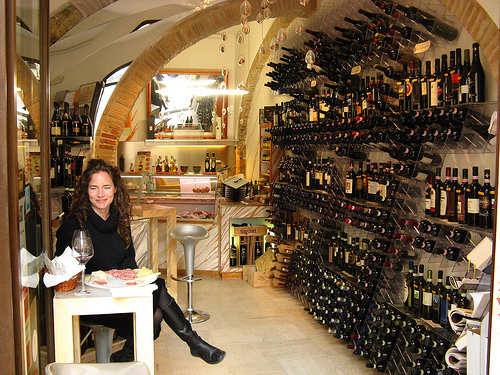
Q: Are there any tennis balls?
A: No, there are no tennis balls.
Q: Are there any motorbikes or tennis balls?
A: No, there are no tennis balls or motorbikes.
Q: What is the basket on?
A: The basket is on the table.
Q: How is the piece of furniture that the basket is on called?
A: The piece of furniture is a table.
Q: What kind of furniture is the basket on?
A: The basket is on the table.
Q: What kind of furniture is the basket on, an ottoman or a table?
A: The basket is on a table.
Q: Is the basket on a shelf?
A: No, the basket is on the table.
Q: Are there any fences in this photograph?
A: No, there are no fences.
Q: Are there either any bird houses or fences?
A: No, there are no fences or bird houses.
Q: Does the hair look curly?
A: Yes, the hair is curly.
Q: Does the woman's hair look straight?
A: No, the hair is curly.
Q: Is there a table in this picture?
A: Yes, there is a table.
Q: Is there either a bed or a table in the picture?
A: Yes, there is a table.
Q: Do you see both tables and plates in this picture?
A: Yes, there are both a table and a plate.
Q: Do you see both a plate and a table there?
A: Yes, there are both a table and a plate.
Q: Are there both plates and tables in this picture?
A: Yes, there are both a table and a plate.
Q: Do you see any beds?
A: No, there are no beds.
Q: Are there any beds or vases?
A: No, there are no beds or vases.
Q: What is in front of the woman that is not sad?
A: The table is in front of the woman.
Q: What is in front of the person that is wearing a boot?
A: The table is in front of the woman.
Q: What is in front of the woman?
A: The table is in front of the woman.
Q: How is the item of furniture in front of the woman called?
A: The piece of furniture is a table.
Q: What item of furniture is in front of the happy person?
A: The piece of furniture is a table.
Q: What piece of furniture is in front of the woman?
A: The piece of furniture is a table.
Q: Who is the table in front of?
A: The table is in front of the woman.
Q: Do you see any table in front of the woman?
A: Yes, there is a table in front of the woman.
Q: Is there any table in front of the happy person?
A: Yes, there is a table in front of the woman.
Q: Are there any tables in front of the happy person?
A: Yes, there is a table in front of the woman.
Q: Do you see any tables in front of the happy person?
A: Yes, there is a table in front of the woman.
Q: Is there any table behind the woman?
A: No, the table is in front of the woman.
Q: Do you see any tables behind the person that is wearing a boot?
A: No, the table is in front of the woman.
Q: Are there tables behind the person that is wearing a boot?
A: No, the table is in front of the woman.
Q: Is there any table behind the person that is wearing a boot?
A: No, the table is in front of the woman.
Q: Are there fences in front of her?
A: No, there is a table in front of the woman.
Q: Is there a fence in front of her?
A: No, there is a table in front of the woman.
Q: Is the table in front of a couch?
A: No, the table is in front of a woman.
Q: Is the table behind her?
A: No, the table is in front of a woman.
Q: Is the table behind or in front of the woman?
A: The table is in front of the woman.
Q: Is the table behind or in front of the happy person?
A: The table is in front of the woman.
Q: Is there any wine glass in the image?
A: Yes, there is a wine glass.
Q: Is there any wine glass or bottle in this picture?
A: Yes, there is a wine glass.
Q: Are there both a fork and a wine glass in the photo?
A: No, there is a wine glass but no forks.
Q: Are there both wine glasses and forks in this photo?
A: No, there is a wine glass but no forks.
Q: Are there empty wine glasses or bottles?
A: Yes, there is an empty wine glass.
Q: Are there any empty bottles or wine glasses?
A: Yes, there is an empty wine glass.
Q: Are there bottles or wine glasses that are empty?
A: Yes, the wine glass is empty.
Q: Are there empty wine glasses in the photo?
A: Yes, there is an empty wine glass.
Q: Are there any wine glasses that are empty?
A: Yes, there is a wine glass that is empty.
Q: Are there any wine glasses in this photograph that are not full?
A: Yes, there is a empty wine glass.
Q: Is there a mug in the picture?
A: No, there are no mugs.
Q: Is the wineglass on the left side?
A: Yes, the wineglass is on the left of the image.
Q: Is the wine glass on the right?
A: No, the wine glass is on the left of the image.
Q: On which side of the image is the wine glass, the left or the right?
A: The wine glass is on the left of the image.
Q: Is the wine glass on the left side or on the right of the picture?
A: The wine glass is on the left of the image.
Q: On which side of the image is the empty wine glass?
A: The wine glass is on the left of the image.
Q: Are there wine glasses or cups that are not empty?
A: No, there is a wine glass but it is empty.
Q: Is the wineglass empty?
A: Yes, the wineglass is empty.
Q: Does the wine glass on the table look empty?
A: Yes, the wine glass is empty.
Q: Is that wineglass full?
A: No, the wineglass is empty.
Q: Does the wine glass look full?
A: No, the wine glass is empty.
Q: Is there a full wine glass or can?
A: No, there is a wine glass but it is empty.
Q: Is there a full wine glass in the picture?
A: No, there is a wine glass but it is empty.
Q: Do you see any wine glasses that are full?
A: No, there is a wine glass but it is empty.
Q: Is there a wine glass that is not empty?
A: No, there is a wine glass but it is empty.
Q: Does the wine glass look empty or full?
A: The wine glass is empty.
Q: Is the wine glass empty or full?
A: The wine glass is empty.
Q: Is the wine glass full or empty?
A: The wine glass is empty.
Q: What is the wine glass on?
A: The wine glass is on the table.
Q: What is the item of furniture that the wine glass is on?
A: The piece of furniture is a table.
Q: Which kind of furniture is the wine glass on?
A: The wine glass is on the table.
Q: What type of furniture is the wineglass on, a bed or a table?
A: The wineglass is on a table.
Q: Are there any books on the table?
A: No, there is a wine glass on the table.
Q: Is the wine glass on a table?
A: Yes, the wine glass is on a table.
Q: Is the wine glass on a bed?
A: No, the wine glass is on a table.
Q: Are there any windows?
A: Yes, there is a window.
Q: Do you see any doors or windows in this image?
A: Yes, there is a window.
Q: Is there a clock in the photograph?
A: No, there are no clocks.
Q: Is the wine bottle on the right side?
A: Yes, the wine bottle is on the right of the image.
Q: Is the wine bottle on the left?
A: No, the wine bottle is on the right of the image.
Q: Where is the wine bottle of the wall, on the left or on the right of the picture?
A: The wine bottle is on the right of the image.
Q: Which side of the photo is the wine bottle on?
A: The wine bottle is on the right of the image.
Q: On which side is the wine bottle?
A: The wine bottle is on the right of the image.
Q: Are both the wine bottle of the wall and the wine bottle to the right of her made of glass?
A: Yes, both the wine bottle and the wine bottle are made of glass.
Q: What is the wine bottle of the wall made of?
A: The wine bottle is made of glass.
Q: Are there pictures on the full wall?
A: No, there is a wine bottle on the wall.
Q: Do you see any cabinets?
A: No, there are no cabinets.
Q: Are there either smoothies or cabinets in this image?
A: No, there are no cabinets or smoothies.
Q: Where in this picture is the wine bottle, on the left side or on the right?
A: The wine bottle is on the right of the image.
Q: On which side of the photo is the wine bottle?
A: The wine bottle is on the right of the image.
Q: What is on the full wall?
A: The wine bottle is on the wall.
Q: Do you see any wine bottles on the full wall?
A: Yes, there is a wine bottle on the wall.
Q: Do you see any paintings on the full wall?
A: No, there is a wine bottle on the wall.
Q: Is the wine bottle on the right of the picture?
A: Yes, the wine bottle is on the right of the image.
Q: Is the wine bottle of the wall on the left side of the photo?
A: No, the wine bottle is on the right of the image.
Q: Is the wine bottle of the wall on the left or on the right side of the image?
A: The wine bottle is on the right of the image.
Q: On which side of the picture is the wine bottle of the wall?
A: The wine bottle is on the right of the image.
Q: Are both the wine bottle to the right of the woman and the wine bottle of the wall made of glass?
A: Yes, both the wine bottle and the wine bottle are made of glass.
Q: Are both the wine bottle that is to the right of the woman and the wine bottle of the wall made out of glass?
A: Yes, both the wine bottle and the wine bottle are made of glass.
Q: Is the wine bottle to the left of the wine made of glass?
A: Yes, the wine bottle is made of glass.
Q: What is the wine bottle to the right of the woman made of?
A: The wine bottle is made of glass.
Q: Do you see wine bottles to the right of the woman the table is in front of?
A: Yes, there is a wine bottle to the right of the woman.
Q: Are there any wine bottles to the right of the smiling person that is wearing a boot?
A: Yes, there is a wine bottle to the right of the woman.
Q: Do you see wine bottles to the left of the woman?
A: No, the wine bottle is to the right of the woman.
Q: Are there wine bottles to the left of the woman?
A: No, the wine bottle is to the right of the woman.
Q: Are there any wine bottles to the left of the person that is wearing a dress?
A: No, the wine bottle is to the right of the woman.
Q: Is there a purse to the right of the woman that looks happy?
A: No, there is a wine bottle to the right of the woman.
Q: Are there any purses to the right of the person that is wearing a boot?
A: No, there is a wine bottle to the right of the woman.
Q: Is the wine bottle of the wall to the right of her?
A: Yes, the wine bottle is to the right of the woman.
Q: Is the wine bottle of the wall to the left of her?
A: No, the wine bottle is to the right of a woman.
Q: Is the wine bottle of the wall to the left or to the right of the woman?
A: The wine bottle is to the right of the woman.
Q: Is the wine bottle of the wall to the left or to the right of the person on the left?
A: The wine bottle is to the right of the woman.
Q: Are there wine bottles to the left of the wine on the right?
A: Yes, there is a wine bottle to the left of the wine.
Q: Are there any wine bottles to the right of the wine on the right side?
A: No, the wine bottle is to the left of the wine.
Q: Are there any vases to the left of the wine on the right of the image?
A: No, there is a wine bottle to the left of the wine.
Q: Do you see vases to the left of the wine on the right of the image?
A: No, there is a wine bottle to the left of the wine.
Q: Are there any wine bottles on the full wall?
A: Yes, there is a wine bottle on the wall.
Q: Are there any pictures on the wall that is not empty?
A: No, there is a wine bottle on the wall.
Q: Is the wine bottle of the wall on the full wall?
A: Yes, the wine bottle is on the wall.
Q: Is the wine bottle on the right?
A: Yes, the wine bottle is on the right of the image.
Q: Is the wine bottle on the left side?
A: No, the wine bottle is on the right of the image.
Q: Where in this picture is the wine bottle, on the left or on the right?
A: The wine bottle is on the right of the image.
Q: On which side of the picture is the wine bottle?
A: The wine bottle is on the right of the image.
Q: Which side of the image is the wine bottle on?
A: The wine bottle is on the right of the image.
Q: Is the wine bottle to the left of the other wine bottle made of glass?
A: Yes, the wine bottle is made of glass.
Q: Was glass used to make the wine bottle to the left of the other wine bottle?
A: Yes, the wine bottle is made of glass.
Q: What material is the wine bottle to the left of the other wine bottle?
A: The wine bottle is made of glass.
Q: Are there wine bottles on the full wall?
A: Yes, there is a wine bottle on the wall.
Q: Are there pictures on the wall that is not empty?
A: No, there is a wine bottle on the wall.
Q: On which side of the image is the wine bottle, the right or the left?
A: The wine bottle is on the right of the image.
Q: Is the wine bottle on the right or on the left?
A: The wine bottle is on the right of the image.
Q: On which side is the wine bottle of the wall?
A: The wine bottle is on the right of the image.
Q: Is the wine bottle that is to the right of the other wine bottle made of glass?
A: Yes, the wine bottle is made of glass.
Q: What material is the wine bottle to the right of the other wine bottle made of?
A: The wine bottle is made of glass.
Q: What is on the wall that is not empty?
A: The wine bottle is on the wall.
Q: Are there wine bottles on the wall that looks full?
A: Yes, there is a wine bottle on the wall.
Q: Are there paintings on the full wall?
A: No, there is a wine bottle on the wall.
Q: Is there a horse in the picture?
A: No, there are no horses.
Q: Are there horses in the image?
A: No, there are no horses.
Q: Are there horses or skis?
A: No, there are no horses or skis.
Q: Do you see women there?
A: Yes, there is a woman.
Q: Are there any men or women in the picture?
A: Yes, there is a woman.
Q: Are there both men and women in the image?
A: No, there is a woman but no men.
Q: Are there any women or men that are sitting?
A: Yes, the woman is sitting.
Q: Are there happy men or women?
A: Yes, there is a happy woman.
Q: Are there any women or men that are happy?
A: Yes, the woman is happy.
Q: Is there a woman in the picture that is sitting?
A: Yes, there is a woman that is sitting.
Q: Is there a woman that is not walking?
A: Yes, there is a woman that is sitting.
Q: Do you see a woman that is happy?
A: Yes, there is a happy woman.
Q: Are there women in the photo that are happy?
A: Yes, there is a woman that is happy.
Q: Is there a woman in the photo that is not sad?
A: Yes, there is a happy woman.